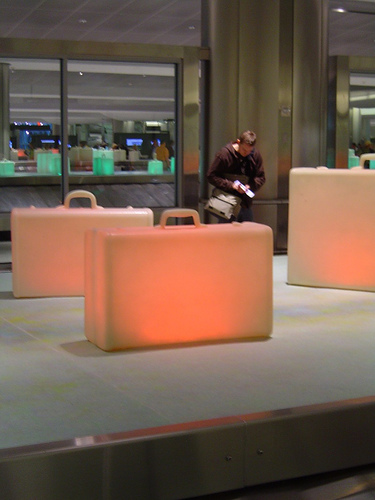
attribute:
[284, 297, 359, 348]
paint — yellow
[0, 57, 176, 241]
window — double pane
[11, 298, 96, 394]
paint — yellow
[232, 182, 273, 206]
object — white 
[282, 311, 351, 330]
paint — yellow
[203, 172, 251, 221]
bag — tan , black 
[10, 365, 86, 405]
paint — yellow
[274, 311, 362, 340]
paint — yellow